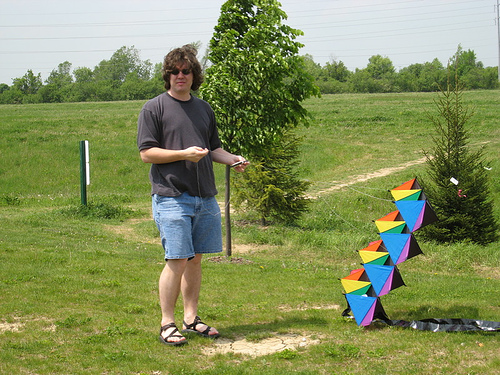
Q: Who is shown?
A: Man.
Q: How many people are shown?
A: One.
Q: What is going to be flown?
A: Kite.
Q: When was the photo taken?
A: Daytime.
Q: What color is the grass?
A: Green.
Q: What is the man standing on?
A: Grass.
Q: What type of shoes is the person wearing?
A: Sandals.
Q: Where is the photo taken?
A: Field.